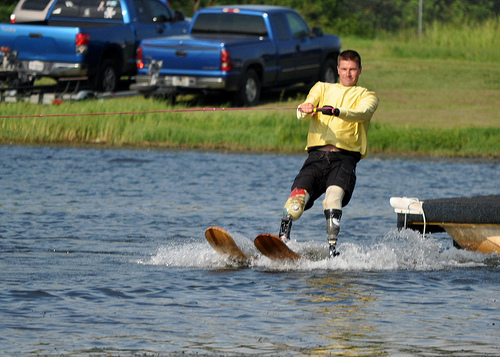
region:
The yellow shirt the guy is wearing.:
[304, 74, 371, 156]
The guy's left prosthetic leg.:
[266, 186, 316, 243]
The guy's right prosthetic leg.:
[318, 187, 342, 251]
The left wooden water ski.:
[192, 224, 242, 263]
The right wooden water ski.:
[250, 236, 304, 263]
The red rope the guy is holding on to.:
[7, 99, 309, 119]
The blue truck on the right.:
[140, 8, 342, 94]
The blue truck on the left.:
[4, 0, 154, 96]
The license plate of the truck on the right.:
[171, 75, 192, 85]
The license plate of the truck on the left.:
[23, 52, 46, 74]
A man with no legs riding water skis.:
[243, 39, 397, 263]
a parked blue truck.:
[124, 12, 343, 119]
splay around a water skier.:
[100, 211, 418, 301]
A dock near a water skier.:
[382, 178, 497, 265]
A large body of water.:
[3, 146, 498, 351]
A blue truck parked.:
[0, 1, 211, 91]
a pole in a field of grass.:
[410, 0, 432, 50]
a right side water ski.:
[199, 221, 252, 266]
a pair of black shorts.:
[284, 147, 373, 214]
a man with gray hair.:
[324, 50, 378, 85]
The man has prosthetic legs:
[245, 167, 369, 267]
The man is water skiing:
[192, 227, 332, 292]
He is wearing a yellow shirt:
[295, 72, 392, 158]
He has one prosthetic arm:
[319, 105, 344, 120]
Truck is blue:
[126, 5, 350, 102]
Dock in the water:
[382, 165, 495, 276]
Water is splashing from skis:
[136, 224, 238, 288]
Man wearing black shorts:
[271, 145, 378, 221]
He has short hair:
[332, 42, 377, 89]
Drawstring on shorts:
[318, 150, 334, 164]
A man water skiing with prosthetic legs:
[244, 177, 373, 285]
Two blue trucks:
[6, 4, 301, 106]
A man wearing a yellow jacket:
[294, 45, 379, 170]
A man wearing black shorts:
[291, 122, 361, 207]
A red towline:
[14, 98, 344, 123]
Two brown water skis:
[180, 216, 312, 282]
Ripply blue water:
[12, 156, 144, 331]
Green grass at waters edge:
[6, 117, 278, 188]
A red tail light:
[208, 40, 237, 80]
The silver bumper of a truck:
[127, 66, 239, 104]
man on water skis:
[230, 51, 366, 284]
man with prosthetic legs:
[276, 43, 385, 285]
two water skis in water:
[180, 217, 338, 297]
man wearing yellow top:
[299, 46, 404, 168]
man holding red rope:
[93, 44, 402, 153]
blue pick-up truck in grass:
[132, 10, 355, 104]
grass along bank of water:
[64, 99, 246, 191]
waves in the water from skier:
[128, 206, 425, 313]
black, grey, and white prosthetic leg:
[309, 186, 367, 284]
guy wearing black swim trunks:
[303, 41, 423, 233]